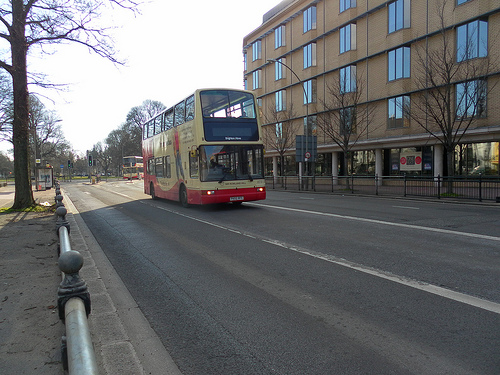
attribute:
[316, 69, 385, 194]
tree — bare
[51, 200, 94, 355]
rail — grey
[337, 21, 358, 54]
windows — crystal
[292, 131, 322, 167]
sign — white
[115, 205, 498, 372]
road — dark grey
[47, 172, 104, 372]
silver/metal fence — silver, black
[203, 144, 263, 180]
windshields — bus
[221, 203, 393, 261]
lines — white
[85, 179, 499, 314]
line — white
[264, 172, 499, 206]
fence — black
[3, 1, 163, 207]
trees — many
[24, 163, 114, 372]
fence — dark black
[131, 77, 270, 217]
bus — red, yellow